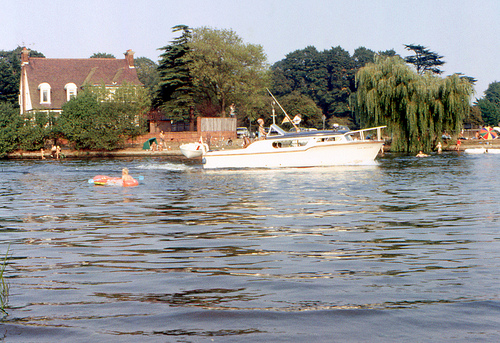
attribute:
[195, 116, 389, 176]
boat — big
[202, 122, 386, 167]
boat — white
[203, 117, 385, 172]
boat — white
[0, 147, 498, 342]
water — calm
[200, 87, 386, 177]
boat — large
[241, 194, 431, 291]
lake — ripples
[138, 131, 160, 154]
tent — green, shade tent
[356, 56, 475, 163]
tree — Big, beautiful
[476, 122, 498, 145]
umbrella — multi-colored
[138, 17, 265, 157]
tree — big, bushy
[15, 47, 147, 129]
house — big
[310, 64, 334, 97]
leaves — dark green